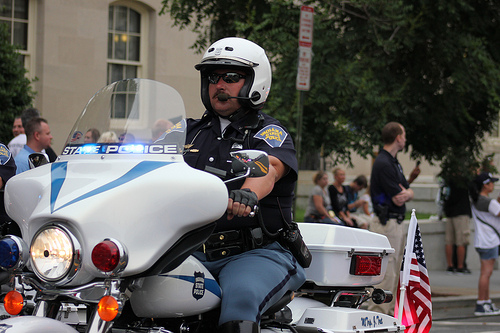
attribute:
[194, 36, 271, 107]
helmet — white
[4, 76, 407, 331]
motorcycle — white, police property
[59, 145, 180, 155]
logo — "state police"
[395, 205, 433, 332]
flag — american, small, red, blue, white,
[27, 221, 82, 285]
headlight — on, white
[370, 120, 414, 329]
man — standing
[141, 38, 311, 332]
policeman — working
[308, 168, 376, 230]
people — sitting, grouped, watching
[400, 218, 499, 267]
wall — concrete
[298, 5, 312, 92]
sign — red, white, state police, special messages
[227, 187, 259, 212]
gloves — fingerless, leather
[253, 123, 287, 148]
patch — state police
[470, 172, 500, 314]
female — staring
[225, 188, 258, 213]
glove — black, fingerless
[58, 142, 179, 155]
sign — painted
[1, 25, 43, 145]
tree — small, green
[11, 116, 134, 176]
people — standing, observing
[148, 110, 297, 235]
shirt — blue, uniform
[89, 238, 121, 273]
light — red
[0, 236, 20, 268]
light — blue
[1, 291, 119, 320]
lights — round, orange